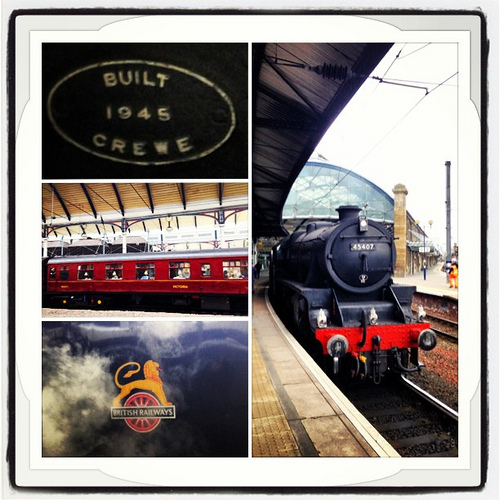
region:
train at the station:
[269, 194, 446, 385]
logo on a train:
[101, 352, 181, 434]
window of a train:
[220, 255, 249, 279]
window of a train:
[196, 261, 213, 278]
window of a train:
[166, 260, 198, 282]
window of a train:
[132, 260, 156, 280]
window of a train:
[102, 261, 125, 279]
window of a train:
[75, 262, 98, 282]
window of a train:
[47, 263, 72, 280]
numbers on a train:
[349, 240, 379, 249]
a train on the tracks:
[278, 203, 457, 456]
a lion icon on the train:
[100, 353, 180, 434]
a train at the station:
[44, 232, 249, 302]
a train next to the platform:
[257, 193, 438, 381]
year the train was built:
[46, 56, 236, 168]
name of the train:
[111, 357, 178, 435]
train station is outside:
[255, 43, 460, 455]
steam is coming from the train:
[42, 321, 111, 456]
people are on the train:
[49, 258, 246, 284]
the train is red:
[48, 255, 245, 292]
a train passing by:
[257, 173, 458, 398]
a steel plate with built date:
[44, 50, 241, 177]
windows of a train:
[46, 243, 261, 284]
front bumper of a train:
[320, 310, 443, 383]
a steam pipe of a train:
[332, 173, 366, 226]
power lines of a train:
[307, 52, 417, 184]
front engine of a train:
[326, 210, 401, 297]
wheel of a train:
[345, 364, 415, 396]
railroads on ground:
[356, 391, 465, 456]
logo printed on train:
[89, 345, 183, 430]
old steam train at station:
[260, 214, 420, 386]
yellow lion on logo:
[109, 363, 166, 410]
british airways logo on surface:
[119, 363, 176, 423]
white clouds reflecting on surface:
[44, 320, 149, 455]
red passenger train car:
[43, 244, 246, 297]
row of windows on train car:
[58, 267, 240, 284]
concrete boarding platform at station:
[250, 294, 332, 464]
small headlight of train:
[353, 216, 368, 230]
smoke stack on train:
[330, 198, 358, 214]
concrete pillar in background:
[390, 178, 412, 258]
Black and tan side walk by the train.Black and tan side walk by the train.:
[248, 298, 255, 396]